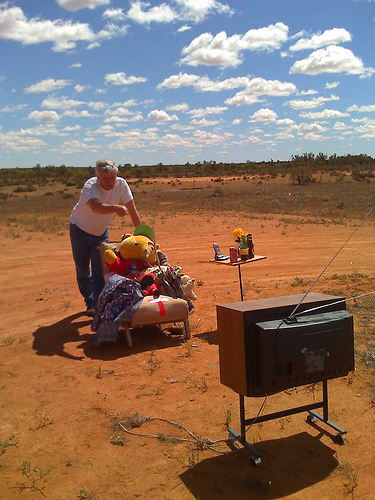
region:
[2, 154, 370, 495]
A man in the desert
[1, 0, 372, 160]
Many white clouds in the sky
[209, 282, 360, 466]
A brown and black TV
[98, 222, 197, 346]
Teddy bear on a chair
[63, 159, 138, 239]
Man wearing a white shirt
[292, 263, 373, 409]
Patches of grass on the dirt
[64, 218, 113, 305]
A pair of blue jeans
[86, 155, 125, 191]
White hair on man's head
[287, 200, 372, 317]
Two television antenas on TV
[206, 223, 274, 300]
Items on a table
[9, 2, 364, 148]
an amazing looking sky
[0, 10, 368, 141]
clouds in the sky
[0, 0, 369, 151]
the clouds are puffy looking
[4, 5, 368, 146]
the clouds are pure white in color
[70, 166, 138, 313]
a man standing up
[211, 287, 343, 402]
a tv looking object being used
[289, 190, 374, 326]
a tv antenna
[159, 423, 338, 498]
the shadow of the tv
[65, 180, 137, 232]
plain white shirt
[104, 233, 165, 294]
a stuffed bear on a chair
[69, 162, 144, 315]
Man wearing white shirt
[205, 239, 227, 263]
Silver phone on table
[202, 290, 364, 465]
Square television on wheels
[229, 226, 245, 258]
Vase with flowers on table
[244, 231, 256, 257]
Brown beer bottle on table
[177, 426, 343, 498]
Shadow of tv on ground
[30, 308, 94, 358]
Man's shadow on ground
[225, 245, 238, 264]
Soda can on table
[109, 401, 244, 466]
Brown rope on ground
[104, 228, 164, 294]
Teddy bear in chair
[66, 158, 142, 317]
man on a desert field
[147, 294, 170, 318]
red tape patch on a chair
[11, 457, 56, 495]
plant in the ground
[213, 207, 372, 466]
television set and antenna on a desert field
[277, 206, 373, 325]
antenna on a television set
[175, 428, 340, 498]
shadow of television on a desert ground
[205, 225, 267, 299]
small table with drinks flowers and a phone on it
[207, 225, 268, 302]
small wooden table on a desert field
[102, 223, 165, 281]
large stuffed bear on a chair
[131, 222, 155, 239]
green hat on a stuffed bear's head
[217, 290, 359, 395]
a black and brown t.v.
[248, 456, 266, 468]
a t.v. cart wheel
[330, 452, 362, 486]
small piece of grass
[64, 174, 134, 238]
a man's white shirt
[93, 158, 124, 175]
a man's gray hair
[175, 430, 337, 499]
a shadow of a t.v.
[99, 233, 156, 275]
a large stuffed animal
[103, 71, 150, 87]
a small white cloud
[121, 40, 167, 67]
part of a blue sky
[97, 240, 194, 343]
part of a chair